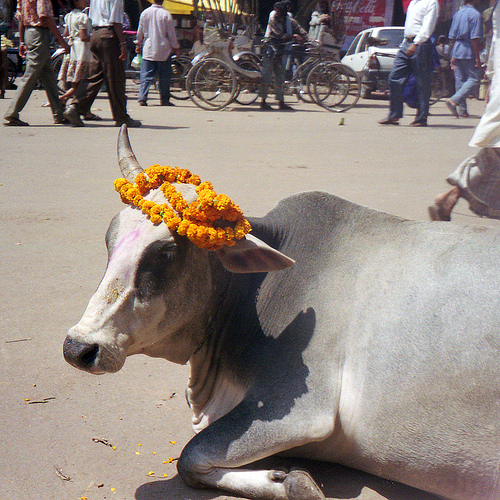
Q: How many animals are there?
A: One.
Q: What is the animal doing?
A: Laying.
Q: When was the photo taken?
A: Afternoon.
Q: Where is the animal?
A: On the ground.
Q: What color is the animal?
A: Gray.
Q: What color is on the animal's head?
A: Orange.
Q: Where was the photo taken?
A: On the street.